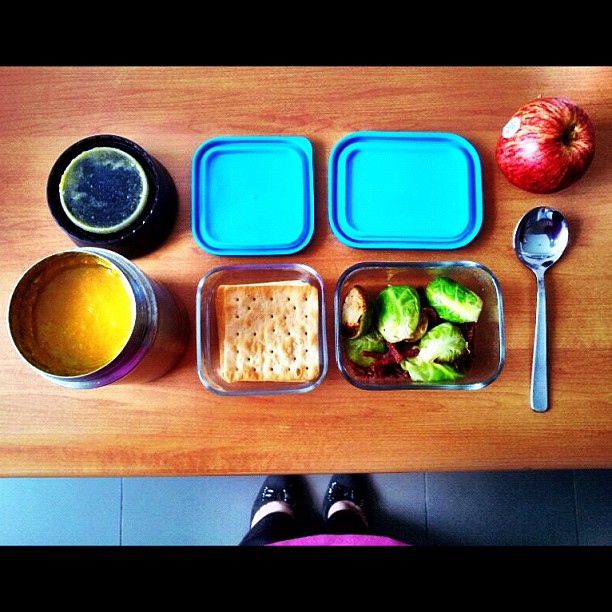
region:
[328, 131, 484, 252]
A more rectangular blue lid.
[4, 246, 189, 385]
A silver container of yellow soup.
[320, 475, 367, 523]
A right black dress shoe.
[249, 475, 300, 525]
A left black dress shoe.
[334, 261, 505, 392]
Rectangle glass container of brussel sprouts.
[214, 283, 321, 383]
Crackers inside a container.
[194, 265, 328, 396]
Smaller square glass container.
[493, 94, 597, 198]
A red apple on the table.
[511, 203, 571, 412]
A silver spoon on the table top.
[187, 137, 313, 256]
Blue square lid.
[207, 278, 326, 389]
saltine cracker in a dish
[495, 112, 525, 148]
sticker on the apple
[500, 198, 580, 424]
spoon on the table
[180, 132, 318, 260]
blue cover to the dish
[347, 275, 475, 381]
salad in the bowl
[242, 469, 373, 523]
black slippers on the feet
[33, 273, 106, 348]
yellow sauce in the can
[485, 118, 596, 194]
apple on the table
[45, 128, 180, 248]
black cover on the table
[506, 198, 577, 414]
Spoon on the table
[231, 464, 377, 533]
black shoes on the feet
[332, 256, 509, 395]
Brussel sprouts in the dish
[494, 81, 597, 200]
Apple on the table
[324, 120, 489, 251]
blue lid on the table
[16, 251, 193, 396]
Soup in the canister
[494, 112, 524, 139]
Sticker on the apple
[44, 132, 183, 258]
Lid to the canister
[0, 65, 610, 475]
Brown table in the room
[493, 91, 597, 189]
red apple on the table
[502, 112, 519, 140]
sticker on the apple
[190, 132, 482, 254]
blue lids to plastic containers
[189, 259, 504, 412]
clear containers on the table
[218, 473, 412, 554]
person standing at the counter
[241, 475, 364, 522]
black shoes person is wearing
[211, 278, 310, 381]
crackers in the clear container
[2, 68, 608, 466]
wood table apple is on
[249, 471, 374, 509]
slippers on the feet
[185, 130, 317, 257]
blue tupperware cover on the table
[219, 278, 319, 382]
saltine cracker in the dish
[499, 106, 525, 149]
sticker on the apple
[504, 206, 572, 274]
Top of a spoon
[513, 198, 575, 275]
Top of a silver spoon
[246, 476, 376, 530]
Shoes on a woman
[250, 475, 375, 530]
Black shoes on a woman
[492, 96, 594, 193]
Red apple with sticker on table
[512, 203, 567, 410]
Spoon on table next to food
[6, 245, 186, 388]
Soup in a thermous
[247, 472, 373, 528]
Feet of person standing next to table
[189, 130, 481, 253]
Blue plastic lids for food containers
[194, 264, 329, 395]
Crackers in a glass container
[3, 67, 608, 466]
Table that has lunch items on it.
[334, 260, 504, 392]
Glass container holding brussell sprouts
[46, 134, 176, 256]
Lid from soup container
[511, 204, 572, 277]
Top of a spoon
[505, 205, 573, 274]
Top of a silver spoon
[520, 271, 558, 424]
Bottom of a silver spoon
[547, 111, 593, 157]
Top of a apple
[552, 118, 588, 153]
Top of a red apple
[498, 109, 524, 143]
Sticker on an apple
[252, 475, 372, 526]
Shoes on a woman